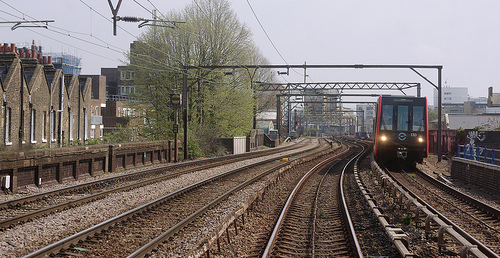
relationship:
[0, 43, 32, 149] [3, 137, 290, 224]
building by track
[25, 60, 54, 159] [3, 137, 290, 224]
building by track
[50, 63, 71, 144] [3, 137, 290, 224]
building by track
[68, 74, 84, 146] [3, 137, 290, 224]
building by track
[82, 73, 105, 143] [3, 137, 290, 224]
building by track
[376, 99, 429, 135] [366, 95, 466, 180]
windshield in front of train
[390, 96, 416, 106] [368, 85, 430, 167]
window in front of train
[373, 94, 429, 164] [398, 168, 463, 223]
train on tracks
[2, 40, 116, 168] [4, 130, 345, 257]
building beside tracks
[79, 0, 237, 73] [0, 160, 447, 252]
power lines over tracks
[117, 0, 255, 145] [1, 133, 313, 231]
green trees beside track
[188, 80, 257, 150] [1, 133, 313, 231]
trees beside track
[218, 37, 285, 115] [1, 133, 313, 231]
trees beside track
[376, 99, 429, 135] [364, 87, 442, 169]
windshield in front of train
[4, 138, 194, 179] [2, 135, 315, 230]
fence beside tracks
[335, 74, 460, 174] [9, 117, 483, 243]
train on track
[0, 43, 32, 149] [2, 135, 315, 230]
building lining tracks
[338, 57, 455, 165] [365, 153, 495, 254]
caboose on track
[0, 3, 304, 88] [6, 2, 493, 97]
power lines in sky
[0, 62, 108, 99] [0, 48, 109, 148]
roofs on houses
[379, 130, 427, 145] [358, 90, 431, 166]
headlights on front of train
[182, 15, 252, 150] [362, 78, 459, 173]
green trees on train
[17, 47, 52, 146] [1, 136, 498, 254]
building lining tracks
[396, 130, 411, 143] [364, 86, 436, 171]
logo on train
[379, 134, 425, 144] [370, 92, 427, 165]
headlights on train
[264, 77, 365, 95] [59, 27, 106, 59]
structure with power lines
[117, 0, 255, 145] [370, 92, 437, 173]
green trees with train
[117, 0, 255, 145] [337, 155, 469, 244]
green trees with tracks